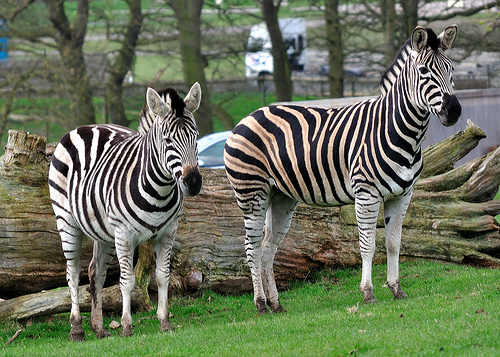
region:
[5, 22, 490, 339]
zebra standing in front of fallen tree trunk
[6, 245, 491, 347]
hooves on green grass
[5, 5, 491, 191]
trees and vehicles in back of zebras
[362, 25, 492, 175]
calm water in back of zebra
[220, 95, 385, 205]
brown stripes between black stripes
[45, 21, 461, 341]
one zebra larger than the other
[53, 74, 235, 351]
a zebra standing outside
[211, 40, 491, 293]
a zebra standing outside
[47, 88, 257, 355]
a zebra with stripes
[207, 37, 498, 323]
a zebra with stripes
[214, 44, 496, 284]
black and white zebra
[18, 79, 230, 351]
black and white zebra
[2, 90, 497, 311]
a tree log on the ground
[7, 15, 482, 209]
trees with no leaves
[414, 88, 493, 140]
a body of water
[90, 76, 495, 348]
two zebras standing outside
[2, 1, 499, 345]
a scene during the day time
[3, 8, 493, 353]
a scene at a zoo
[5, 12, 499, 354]
an image during the day time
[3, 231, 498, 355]
a green yard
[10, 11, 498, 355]
two zebras standing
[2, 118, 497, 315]
a large wood log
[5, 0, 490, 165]
some trees in the background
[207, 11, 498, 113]
a group of vehicles in the distance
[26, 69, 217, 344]
a zebra on the left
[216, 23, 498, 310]
a zebra on the right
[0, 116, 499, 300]
Large log behind two zebras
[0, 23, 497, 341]
Two zebras standing in the grass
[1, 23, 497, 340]
Two zebras standing in front of log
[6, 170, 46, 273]
Green patch on side of log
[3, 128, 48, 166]
Stump on top of log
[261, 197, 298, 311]
White underside of zebra's leg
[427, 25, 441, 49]
Black tuft of mane on zebra's head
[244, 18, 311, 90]
White semi cab in the background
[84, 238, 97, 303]
Long tail next to zebra's leg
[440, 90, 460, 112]
Black spot on zebra's face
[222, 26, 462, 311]
black and white zebra standing in grass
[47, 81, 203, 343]
black and white zebra standing in grass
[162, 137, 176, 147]
a zebra's right eye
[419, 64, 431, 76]
a zebra's right eye